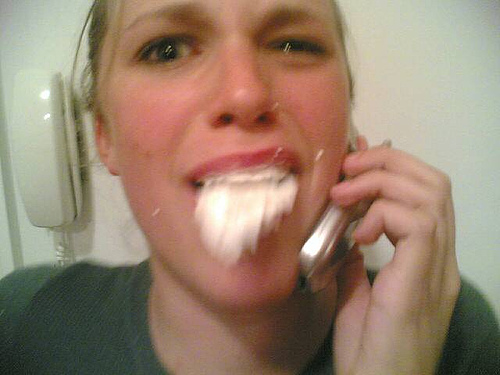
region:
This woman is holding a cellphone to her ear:
[337, 105, 362, 332]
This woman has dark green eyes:
[138, 20, 208, 67]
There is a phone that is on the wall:
[5, 62, 92, 242]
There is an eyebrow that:
[136, 5, 217, 40]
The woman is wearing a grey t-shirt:
[35, 253, 95, 350]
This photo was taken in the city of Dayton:
[76, 35, 372, 365]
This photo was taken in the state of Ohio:
[71, 15, 418, 373]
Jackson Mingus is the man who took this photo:
[53, 12, 425, 353]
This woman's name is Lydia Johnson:
[41, 27, 408, 371]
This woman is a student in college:
[56, 68, 434, 338]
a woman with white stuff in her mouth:
[146, 139, 332, 279]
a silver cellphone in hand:
[308, 105, 478, 367]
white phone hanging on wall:
[2, 43, 97, 274]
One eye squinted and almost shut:
[258, 23, 345, 80]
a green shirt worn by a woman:
[20, 256, 499, 373]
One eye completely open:
[124, 18, 205, 80]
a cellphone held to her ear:
[303, 74, 413, 298]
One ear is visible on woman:
[80, 74, 146, 202]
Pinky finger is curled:
[353, 196, 435, 291]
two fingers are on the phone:
[323, 137, 473, 239]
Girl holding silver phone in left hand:
[300, 147, 472, 364]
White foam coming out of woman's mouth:
[191, 163, 299, 268]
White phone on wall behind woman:
[7, 57, 92, 266]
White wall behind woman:
[5, 5, 495, 295]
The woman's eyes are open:
[122, 15, 356, 78]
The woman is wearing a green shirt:
[0, 260, 495, 367]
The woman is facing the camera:
[83, 3, 433, 320]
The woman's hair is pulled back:
[56, 1, 378, 121]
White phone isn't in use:
[6, 63, 95, 263]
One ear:
[80, 101, 138, 188]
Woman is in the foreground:
[1, 1, 496, 373]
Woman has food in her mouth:
[165, 156, 315, 269]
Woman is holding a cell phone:
[261, 119, 386, 295]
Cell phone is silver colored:
[298, 101, 395, 301]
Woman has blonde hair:
[66, 0, 374, 137]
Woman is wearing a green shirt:
[1, 246, 496, 374]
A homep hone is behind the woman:
[10, 50, 92, 271]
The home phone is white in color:
[3, 63, 88, 258]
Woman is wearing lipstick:
[172, 132, 304, 193]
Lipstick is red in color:
[171, 146, 315, 193]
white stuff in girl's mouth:
[173, 163, 310, 260]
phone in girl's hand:
[283, 130, 421, 315]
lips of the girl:
[193, 133, 293, 193]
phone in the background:
[0, 72, 72, 247]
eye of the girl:
[123, 16, 219, 91]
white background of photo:
[382, 33, 489, 105]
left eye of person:
[248, 10, 325, 86]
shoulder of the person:
[25, 258, 125, 331]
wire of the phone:
[29, 231, 80, 280]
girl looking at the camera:
[116, 20, 357, 227]